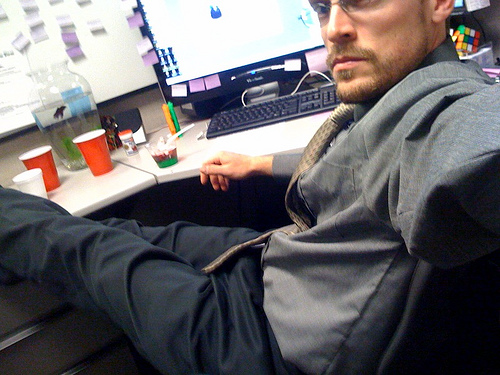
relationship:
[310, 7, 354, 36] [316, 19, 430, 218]
nose of man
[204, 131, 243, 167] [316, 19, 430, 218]
hand of man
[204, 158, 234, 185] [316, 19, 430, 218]
thumb of man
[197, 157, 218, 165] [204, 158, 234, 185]
nail on thumb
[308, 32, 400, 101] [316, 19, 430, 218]
mouth of man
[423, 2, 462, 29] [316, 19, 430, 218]
ear of man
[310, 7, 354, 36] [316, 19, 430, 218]
eye of man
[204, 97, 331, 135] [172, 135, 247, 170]
keyboard on desk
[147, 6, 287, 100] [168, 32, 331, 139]
monitor on desktop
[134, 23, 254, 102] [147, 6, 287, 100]
note on monitor